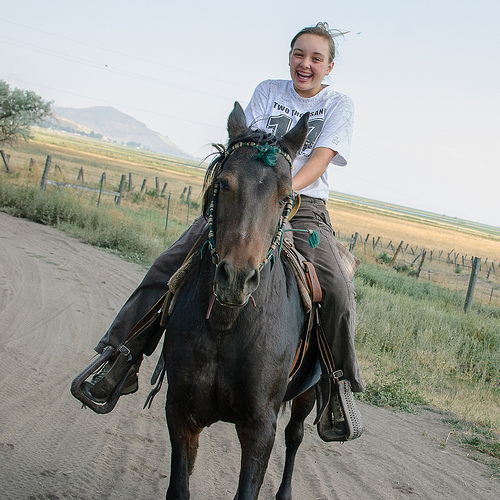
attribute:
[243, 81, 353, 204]
shirt — white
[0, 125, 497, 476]
grass — short, brown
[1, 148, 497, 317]
fence — wooden, barbed, long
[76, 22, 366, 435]
girl — smiling, young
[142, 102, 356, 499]
horse — dark brown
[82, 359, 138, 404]
shoe — brown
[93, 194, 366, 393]
pants — gray, dark grey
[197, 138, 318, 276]
bridle — decorative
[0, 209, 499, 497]
dirt — brown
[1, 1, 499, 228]
sky — bright